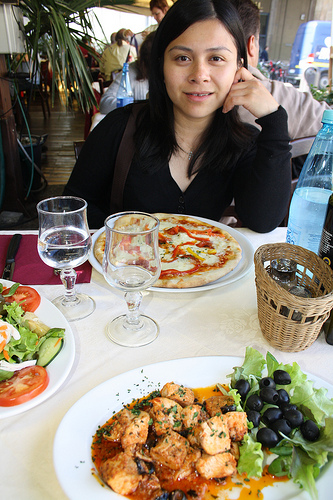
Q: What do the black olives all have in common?
A: A hole.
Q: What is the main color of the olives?
A: Black.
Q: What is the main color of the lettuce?
A: Green.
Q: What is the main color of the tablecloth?
A: White.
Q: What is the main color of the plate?
A: White.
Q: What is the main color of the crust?
A: Brown.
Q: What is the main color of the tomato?
A: Red.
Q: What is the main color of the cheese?
A: White.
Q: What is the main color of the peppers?
A: Red.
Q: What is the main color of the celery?
A: Green.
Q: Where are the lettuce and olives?
A: On plate.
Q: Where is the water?
A: On table.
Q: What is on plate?
A: Salad.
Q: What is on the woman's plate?
A: Pizza.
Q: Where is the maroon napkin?
A: On table.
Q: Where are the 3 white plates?
A: On table.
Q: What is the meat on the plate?
A: Chicken.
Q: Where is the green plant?
A: In background.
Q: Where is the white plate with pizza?
A: In front of woman.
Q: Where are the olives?
A: Next to chicken.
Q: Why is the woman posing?
A: For the camera.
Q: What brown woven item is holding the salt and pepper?
A: Basket.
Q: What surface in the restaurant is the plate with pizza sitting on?
A: Table.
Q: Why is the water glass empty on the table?
A: It got drank.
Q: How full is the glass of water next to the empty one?
A: Half full.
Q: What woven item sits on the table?
A: Basket.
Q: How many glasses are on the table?
A: 2.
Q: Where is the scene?
A: A restaurant.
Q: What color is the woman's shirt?
A: Black.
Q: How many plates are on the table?
A: 3.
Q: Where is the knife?
A: On a napkin.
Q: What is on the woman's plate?
A: Pizza.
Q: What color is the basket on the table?
A: Brown.